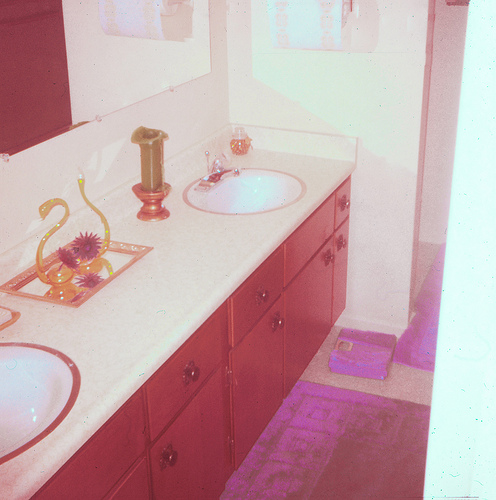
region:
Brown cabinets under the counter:
[132, 186, 337, 486]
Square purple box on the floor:
[324, 316, 402, 395]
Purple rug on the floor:
[232, 370, 418, 491]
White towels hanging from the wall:
[259, 3, 351, 57]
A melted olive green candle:
[126, 129, 181, 201]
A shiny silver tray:
[13, 250, 163, 305]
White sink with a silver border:
[178, 152, 315, 207]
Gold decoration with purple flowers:
[27, 174, 124, 285]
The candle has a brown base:
[131, 126, 197, 245]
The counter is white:
[41, 153, 353, 396]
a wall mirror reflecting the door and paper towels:
[1, 2, 232, 153]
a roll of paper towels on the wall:
[258, 2, 365, 63]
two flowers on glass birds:
[27, 165, 125, 286]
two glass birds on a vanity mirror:
[2, 167, 153, 310]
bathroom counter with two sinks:
[3, 122, 353, 463]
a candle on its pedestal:
[130, 123, 177, 227]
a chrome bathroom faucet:
[197, 145, 241, 194]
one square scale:
[329, 319, 401, 385]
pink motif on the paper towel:
[263, 1, 361, 54]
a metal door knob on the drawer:
[178, 360, 203, 391]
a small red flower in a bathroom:
[57, 246, 80, 276]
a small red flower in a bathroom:
[74, 231, 103, 254]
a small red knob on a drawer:
[186, 363, 200, 379]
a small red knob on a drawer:
[161, 441, 178, 463]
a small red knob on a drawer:
[255, 285, 267, 302]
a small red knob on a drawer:
[271, 311, 287, 329]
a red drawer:
[148, 312, 218, 418]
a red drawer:
[223, 249, 283, 329]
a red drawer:
[333, 183, 352, 221]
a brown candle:
[131, 122, 165, 187]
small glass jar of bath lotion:
[227, 124, 256, 156]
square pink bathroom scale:
[336, 321, 402, 388]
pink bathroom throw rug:
[220, 377, 433, 493]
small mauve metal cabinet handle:
[267, 309, 286, 334]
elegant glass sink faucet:
[197, 145, 233, 189]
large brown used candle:
[126, 124, 167, 187]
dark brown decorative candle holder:
[132, 181, 173, 224]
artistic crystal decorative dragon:
[29, 157, 117, 300]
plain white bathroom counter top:
[148, 251, 201, 301]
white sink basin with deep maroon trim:
[3, 343, 78, 461]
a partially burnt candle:
[129, 119, 171, 189]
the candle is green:
[128, 118, 179, 191]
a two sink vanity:
[0, 113, 359, 492]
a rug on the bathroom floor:
[217, 373, 419, 498]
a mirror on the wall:
[9, 0, 250, 164]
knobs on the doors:
[160, 197, 359, 476]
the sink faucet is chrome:
[197, 143, 246, 187]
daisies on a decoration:
[58, 230, 102, 270]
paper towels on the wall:
[254, 3, 360, 49]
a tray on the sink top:
[6, 233, 154, 305]